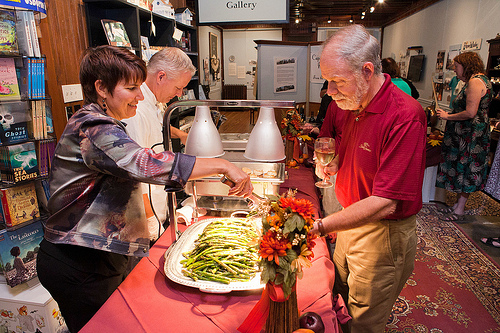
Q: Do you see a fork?
A: No, there are no forks.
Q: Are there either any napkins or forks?
A: No, there are no forks or napkins.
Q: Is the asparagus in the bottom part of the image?
A: Yes, the asparagus is in the bottom of the image.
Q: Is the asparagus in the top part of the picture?
A: No, the asparagus is in the bottom of the image.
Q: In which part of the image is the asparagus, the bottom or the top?
A: The asparagus is in the bottom of the image.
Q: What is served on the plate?
A: The asparagus is served on the plate.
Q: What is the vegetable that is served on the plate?
A: The vegetable is an asparagus.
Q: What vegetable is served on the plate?
A: The vegetable is an asparagus.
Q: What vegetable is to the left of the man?
A: The vegetable is an asparagus.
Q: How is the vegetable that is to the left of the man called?
A: The vegetable is an asparagus.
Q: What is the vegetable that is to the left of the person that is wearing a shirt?
A: The vegetable is an asparagus.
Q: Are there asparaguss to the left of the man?
A: Yes, there is an asparagus to the left of the man.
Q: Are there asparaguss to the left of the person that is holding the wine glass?
A: Yes, there is an asparagus to the left of the man.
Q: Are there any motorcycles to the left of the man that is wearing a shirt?
A: No, there is an asparagus to the left of the man.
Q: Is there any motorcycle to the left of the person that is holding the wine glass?
A: No, there is an asparagus to the left of the man.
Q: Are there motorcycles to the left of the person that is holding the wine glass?
A: No, there is an asparagus to the left of the man.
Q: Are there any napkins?
A: No, there are no napkins.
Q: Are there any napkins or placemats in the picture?
A: No, there are no napkins or placemats.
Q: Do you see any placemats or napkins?
A: No, there are no napkins or placemats.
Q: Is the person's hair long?
A: No, the hair is short.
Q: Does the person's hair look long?
A: No, the hair is short.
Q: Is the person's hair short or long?
A: The hair is short.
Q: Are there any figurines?
A: No, there are no figurines.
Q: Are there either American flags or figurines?
A: No, there are no figurines or American flags.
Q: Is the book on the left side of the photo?
A: Yes, the book is on the left of the image.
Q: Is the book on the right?
A: No, the book is on the left of the image.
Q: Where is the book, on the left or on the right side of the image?
A: The book is on the left of the image.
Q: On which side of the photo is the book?
A: The book is on the left of the image.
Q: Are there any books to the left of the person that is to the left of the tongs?
A: Yes, there is a book to the left of the person.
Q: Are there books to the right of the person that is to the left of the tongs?
A: No, the book is to the left of the person.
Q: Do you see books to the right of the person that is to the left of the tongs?
A: No, the book is to the left of the person.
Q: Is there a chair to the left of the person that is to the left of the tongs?
A: No, there is a book to the left of the person.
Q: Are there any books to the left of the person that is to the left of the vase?
A: Yes, there is a book to the left of the person.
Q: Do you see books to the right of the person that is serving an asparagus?
A: No, the book is to the left of the person.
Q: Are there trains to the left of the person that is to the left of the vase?
A: No, there is a book to the left of the person.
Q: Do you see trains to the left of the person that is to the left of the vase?
A: No, there is a book to the left of the person.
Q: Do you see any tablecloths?
A: Yes, there is a tablecloth.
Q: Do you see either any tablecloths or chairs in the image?
A: Yes, there is a tablecloth.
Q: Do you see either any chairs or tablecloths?
A: Yes, there is a tablecloth.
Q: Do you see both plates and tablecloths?
A: Yes, there are both a tablecloth and a plate.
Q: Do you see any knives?
A: No, there are no knives.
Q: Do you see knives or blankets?
A: No, there are no knives or blankets.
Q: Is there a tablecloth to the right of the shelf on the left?
A: Yes, there is a tablecloth to the right of the shelf.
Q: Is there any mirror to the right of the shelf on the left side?
A: No, there is a tablecloth to the right of the shelf.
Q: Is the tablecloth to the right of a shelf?
A: Yes, the tablecloth is to the right of a shelf.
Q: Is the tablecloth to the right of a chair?
A: No, the tablecloth is to the right of a shelf.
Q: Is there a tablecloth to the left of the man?
A: Yes, there is a tablecloth to the left of the man.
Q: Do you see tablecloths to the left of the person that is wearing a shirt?
A: Yes, there is a tablecloth to the left of the man.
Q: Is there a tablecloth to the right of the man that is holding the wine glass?
A: No, the tablecloth is to the left of the man.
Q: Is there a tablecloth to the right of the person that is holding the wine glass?
A: No, the tablecloth is to the left of the man.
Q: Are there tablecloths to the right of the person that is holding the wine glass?
A: No, the tablecloth is to the left of the man.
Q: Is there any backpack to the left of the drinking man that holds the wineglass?
A: No, there is a tablecloth to the left of the man.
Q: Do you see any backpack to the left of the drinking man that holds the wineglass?
A: No, there is a tablecloth to the left of the man.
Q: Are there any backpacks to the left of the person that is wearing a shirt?
A: No, there is a tablecloth to the left of the man.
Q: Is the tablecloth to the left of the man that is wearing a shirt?
A: Yes, the tablecloth is to the left of the man.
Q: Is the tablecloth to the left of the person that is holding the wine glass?
A: Yes, the tablecloth is to the left of the man.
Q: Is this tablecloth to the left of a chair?
A: No, the tablecloth is to the left of the man.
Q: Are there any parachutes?
A: No, there are no parachutes.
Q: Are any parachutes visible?
A: No, there are no parachutes.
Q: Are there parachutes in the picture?
A: No, there are no parachutes.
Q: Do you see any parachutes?
A: No, there are no parachutes.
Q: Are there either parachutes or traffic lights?
A: No, there are no parachutes or traffic lights.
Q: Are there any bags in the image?
A: No, there are no bags.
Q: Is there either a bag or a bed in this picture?
A: No, there are no bags or beds.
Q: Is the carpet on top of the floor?
A: Yes, the carpet is on top of the floor.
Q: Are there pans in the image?
A: No, there are no pans.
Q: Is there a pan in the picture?
A: No, there are no pans.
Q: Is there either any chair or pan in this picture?
A: No, there are no pans or chairs.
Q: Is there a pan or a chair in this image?
A: No, there are no pans or chairs.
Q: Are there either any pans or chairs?
A: No, there are no pans or chairs.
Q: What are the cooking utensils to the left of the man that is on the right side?
A: The cooking utensils are tongs.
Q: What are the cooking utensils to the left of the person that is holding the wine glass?
A: The cooking utensils are tongs.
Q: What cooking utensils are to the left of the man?
A: The cooking utensils are tongs.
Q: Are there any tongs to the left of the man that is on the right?
A: Yes, there are tongs to the left of the man.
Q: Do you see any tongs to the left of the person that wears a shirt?
A: Yes, there are tongs to the left of the man.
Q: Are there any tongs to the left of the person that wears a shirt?
A: Yes, there are tongs to the left of the man.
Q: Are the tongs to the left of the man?
A: Yes, the tongs are to the left of the man.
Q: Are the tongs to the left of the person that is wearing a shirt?
A: Yes, the tongs are to the left of the man.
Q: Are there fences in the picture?
A: No, there are no fences.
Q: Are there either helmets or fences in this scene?
A: No, there are no fences or helmets.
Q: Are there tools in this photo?
A: No, there are no tools.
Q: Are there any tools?
A: No, there are no tools.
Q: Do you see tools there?
A: No, there are no tools.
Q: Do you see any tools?
A: No, there are no tools.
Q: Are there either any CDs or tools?
A: No, there are no tools or cds.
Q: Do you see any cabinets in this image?
A: No, there are no cabinets.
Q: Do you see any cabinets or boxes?
A: No, there are no cabinets or boxes.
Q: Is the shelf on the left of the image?
A: Yes, the shelf is on the left of the image.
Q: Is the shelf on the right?
A: No, the shelf is on the left of the image.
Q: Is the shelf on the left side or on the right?
A: The shelf is on the left of the image.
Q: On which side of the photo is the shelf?
A: The shelf is on the left of the image.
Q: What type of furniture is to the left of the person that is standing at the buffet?
A: The piece of furniture is a shelf.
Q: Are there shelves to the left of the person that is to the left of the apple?
A: Yes, there is a shelf to the left of the person.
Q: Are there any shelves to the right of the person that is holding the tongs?
A: No, the shelf is to the left of the person.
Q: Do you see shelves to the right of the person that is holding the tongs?
A: No, the shelf is to the left of the person.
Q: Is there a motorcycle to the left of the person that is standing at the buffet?
A: No, there is a shelf to the left of the person.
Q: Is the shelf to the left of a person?
A: Yes, the shelf is to the left of a person.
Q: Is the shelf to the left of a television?
A: No, the shelf is to the left of a person.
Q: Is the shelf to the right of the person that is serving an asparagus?
A: No, the shelf is to the left of the person.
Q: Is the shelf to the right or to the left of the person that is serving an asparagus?
A: The shelf is to the left of the person.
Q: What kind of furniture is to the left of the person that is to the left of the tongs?
A: The piece of furniture is a shelf.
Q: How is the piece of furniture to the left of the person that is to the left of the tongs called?
A: The piece of furniture is a shelf.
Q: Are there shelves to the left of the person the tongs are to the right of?
A: Yes, there is a shelf to the left of the person.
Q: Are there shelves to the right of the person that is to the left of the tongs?
A: No, the shelf is to the left of the person.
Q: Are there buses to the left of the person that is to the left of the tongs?
A: No, there is a shelf to the left of the person.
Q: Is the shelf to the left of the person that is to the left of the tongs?
A: Yes, the shelf is to the left of the person.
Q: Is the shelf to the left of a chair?
A: No, the shelf is to the left of the person.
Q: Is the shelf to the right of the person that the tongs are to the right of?
A: No, the shelf is to the left of the person.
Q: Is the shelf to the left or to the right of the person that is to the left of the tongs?
A: The shelf is to the left of the person.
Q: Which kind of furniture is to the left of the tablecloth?
A: The piece of furniture is a shelf.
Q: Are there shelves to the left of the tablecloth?
A: Yes, there is a shelf to the left of the tablecloth.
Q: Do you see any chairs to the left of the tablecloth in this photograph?
A: No, there is a shelf to the left of the tablecloth.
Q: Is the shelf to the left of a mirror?
A: No, the shelf is to the left of the tablecloth.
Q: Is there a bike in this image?
A: No, there are no bikes.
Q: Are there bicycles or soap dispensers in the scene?
A: No, there are no bicycles or soap dispensers.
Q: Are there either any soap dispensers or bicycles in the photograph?
A: No, there are no bicycles or soap dispensers.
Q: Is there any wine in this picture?
A: Yes, there is wine.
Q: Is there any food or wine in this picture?
A: Yes, there is wine.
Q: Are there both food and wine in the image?
A: Yes, there are both wine and food.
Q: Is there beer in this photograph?
A: No, there is no beer.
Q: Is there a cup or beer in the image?
A: No, there are no beer or cups.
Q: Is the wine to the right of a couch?
A: No, the wine is to the right of the lamp.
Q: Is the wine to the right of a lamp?
A: Yes, the wine is to the right of a lamp.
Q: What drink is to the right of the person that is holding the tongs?
A: The drink is wine.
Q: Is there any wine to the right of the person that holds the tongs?
A: Yes, there is wine to the right of the person.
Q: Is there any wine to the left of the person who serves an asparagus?
A: No, the wine is to the right of the person.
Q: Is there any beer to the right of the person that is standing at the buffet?
A: No, there is wine to the right of the person.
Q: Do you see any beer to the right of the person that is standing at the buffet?
A: No, there is wine to the right of the person.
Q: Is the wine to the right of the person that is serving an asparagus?
A: Yes, the wine is to the right of the person.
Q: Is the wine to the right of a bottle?
A: No, the wine is to the right of the person.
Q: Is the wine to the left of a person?
A: No, the wine is to the right of a person.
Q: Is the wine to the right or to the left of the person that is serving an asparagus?
A: The wine is to the right of the person.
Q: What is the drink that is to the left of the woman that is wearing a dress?
A: The drink is wine.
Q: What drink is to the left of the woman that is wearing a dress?
A: The drink is wine.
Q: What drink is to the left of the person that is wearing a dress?
A: The drink is wine.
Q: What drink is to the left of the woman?
A: The drink is wine.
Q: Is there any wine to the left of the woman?
A: Yes, there is wine to the left of the woman.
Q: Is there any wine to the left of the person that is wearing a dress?
A: Yes, there is wine to the left of the woman.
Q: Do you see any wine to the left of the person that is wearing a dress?
A: Yes, there is wine to the left of the woman.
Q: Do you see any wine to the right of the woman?
A: No, the wine is to the left of the woman.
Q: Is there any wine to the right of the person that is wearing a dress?
A: No, the wine is to the left of the woman.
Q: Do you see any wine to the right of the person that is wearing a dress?
A: No, the wine is to the left of the woman.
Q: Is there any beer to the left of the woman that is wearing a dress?
A: No, there is wine to the left of the woman.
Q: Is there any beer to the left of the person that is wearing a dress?
A: No, there is wine to the left of the woman.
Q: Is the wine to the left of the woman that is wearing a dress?
A: Yes, the wine is to the left of the woman.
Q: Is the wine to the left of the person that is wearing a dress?
A: Yes, the wine is to the left of the woman.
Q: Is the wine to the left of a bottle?
A: No, the wine is to the left of the woman.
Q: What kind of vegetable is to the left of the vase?
A: The vegetable is an asparagus.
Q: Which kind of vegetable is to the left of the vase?
A: The vegetable is an asparagus.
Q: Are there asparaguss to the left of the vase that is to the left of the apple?
A: Yes, there is an asparagus to the left of the vase.